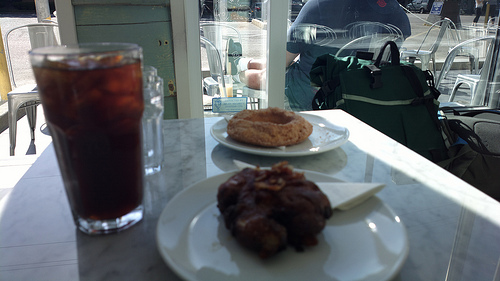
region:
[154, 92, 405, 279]
Plates on a table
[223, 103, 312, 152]
The pastry is light brown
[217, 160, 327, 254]
the pastry is dark brown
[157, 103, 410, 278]
The plates are white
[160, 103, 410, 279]
The plates are round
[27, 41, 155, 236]
Clear glass filled with brown liquid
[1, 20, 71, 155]
The chair is white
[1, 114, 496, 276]
The table is white and grey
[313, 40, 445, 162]
The bag is leaning against the glass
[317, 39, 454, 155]
The bag is green with black straps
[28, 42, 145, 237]
glass full of soda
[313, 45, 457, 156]
black bag sitting on the chair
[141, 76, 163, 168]
small empty glass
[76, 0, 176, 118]
green siding on the wall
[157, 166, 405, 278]
pastry on the round plate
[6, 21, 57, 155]
metal chair sitting outside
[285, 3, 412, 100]
person sitting outside the window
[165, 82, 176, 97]
hole in the paint on the wall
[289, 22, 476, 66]
reflection on the window glass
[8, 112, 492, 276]
white marble counter top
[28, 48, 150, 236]
glass filled with a drink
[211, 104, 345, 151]
plate with circular food on it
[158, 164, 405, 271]
plate with chunk of dark brown food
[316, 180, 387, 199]
white folded napkin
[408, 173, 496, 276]
part of counter to eat on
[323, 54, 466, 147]
green, white and black bag for carrying items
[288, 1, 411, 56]
person sitting down outside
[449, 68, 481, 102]
chair outside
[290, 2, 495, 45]
window with light glare on it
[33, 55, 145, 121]
ice cubes to make drink cold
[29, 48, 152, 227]
a glass on the table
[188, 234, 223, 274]
light on the plate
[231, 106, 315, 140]
a donut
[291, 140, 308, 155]
a white plate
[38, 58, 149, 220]
brown liquid in the glass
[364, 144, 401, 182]
a table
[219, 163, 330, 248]
food on the plate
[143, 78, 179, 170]
a clear glass on the table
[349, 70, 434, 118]
a green bag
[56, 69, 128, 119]
ice in the glass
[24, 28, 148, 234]
dark brown carbonated beverage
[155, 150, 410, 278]
white circled ceramic snack plate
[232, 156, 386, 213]
triangular folded white napkin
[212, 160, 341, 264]
brown sugary cookie snack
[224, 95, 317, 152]
light brown sugary snack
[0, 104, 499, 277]
white granite table top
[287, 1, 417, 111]
man in blue shirt outside window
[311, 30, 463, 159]
green travel bag with straps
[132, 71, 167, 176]
empty clear glass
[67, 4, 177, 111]
green section of wall